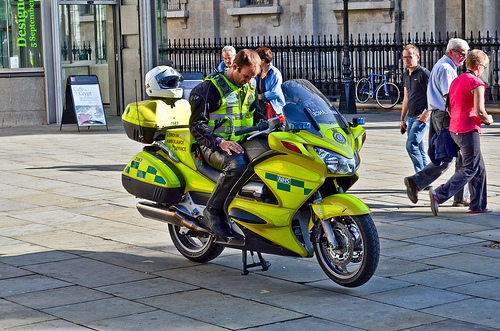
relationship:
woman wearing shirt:
[427, 48, 495, 215] [446, 74, 487, 137]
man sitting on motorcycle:
[189, 47, 266, 239] [121, 78, 379, 288]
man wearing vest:
[189, 47, 266, 239] [202, 72, 256, 144]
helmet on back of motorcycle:
[144, 65, 183, 99] [121, 78, 379, 288]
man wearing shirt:
[401, 43, 433, 190] [399, 65, 431, 118]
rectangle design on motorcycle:
[145, 164, 157, 174] [121, 78, 379, 288]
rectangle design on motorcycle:
[135, 168, 146, 178] [121, 78, 379, 288]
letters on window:
[14, 3, 39, 49] [1, 1, 46, 71]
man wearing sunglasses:
[403, 36, 469, 207] [455, 47, 469, 57]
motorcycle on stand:
[121, 78, 379, 288] [242, 248, 272, 275]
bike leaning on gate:
[354, 64, 400, 109] [160, 31, 498, 103]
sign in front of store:
[58, 74, 110, 133] [1, 0, 174, 131]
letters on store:
[14, 3, 39, 49] [1, 0, 174, 131]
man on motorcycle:
[189, 47, 266, 239] [121, 78, 379, 288]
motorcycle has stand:
[121, 78, 379, 288] [242, 248, 272, 275]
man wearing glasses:
[401, 43, 433, 190] [402, 54, 418, 59]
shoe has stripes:
[429, 188, 440, 215] [433, 192, 439, 203]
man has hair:
[403, 36, 469, 207] [445, 37, 469, 55]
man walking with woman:
[403, 36, 469, 207] [427, 48, 495, 215]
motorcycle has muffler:
[121, 78, 379, 288] [136, 201, 209, 232]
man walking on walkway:
[401, 43, 433, 190] [1, 125, 500, 329]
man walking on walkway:
[403, 36, 469, 207] [1, 125, 500, 329]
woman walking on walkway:
[427, 48, 495, 215] [1, 125, 500, 329]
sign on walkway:
[58, 74, 110, 133] [1, 125, 500, 329]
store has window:
[1, 0, 174, 131] [1, 1, 46, 71]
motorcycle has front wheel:
[121, 78, 379, 288] [310, 214, 380, 288]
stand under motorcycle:
[242, 248, 272, 275] [121, 78, 379, 288]